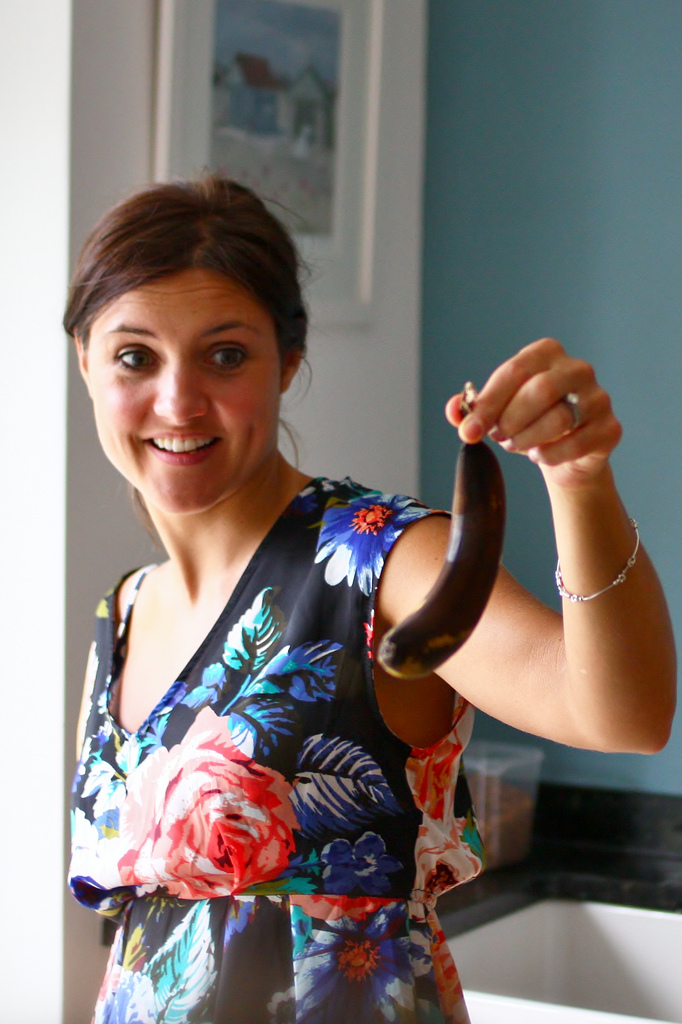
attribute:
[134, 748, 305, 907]
flower — pink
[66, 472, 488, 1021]
dress — black, blue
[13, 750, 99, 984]
wall — side, building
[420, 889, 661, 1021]
sink — white